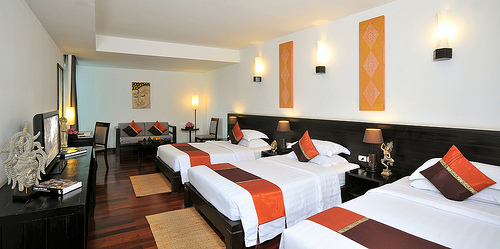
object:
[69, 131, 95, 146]
desk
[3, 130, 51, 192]
art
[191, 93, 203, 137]
lamp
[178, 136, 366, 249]
bed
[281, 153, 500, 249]
bed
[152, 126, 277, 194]
bed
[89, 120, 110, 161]
brown chair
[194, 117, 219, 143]
brown chair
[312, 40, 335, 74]
light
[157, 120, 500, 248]
three beds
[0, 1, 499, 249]
room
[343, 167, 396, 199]
table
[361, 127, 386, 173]
lamp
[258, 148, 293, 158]
table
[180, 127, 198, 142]
table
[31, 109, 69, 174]
television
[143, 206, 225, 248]
carpet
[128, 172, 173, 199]
carpet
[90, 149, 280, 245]
floor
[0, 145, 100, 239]
dresser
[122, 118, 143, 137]
pillow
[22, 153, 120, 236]
book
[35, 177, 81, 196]
book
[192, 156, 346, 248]
bed spread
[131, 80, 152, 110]
picture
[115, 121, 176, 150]
couch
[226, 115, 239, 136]
lamp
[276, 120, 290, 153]
lamp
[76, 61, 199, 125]
wall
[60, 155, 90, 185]
stand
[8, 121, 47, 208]
object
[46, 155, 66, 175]
stand